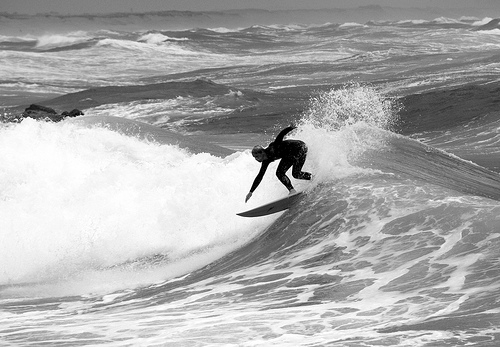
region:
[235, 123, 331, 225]
Man surfing on a wave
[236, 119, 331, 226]
Man standing on surf board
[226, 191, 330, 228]
Surf board on wave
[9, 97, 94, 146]
Rocks coming out of the water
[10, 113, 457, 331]
Large ocean waves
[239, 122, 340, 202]
Man wearing a black wetsuit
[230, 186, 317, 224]
Surf board the man is standing on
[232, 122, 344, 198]
Man with back leg in wave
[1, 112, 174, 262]
Wave crashing into rocks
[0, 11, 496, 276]
Ocean waves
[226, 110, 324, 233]
a black surfer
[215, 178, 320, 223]
a gray surfboard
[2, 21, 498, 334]
a gray beach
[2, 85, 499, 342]
large gray waves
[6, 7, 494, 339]
a scene outside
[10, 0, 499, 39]
a sky with clouds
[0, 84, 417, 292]
white splash of water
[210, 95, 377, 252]
a surfer riding a wave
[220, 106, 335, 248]
a surfer on top of a wave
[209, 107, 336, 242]
a surfer on a surfboard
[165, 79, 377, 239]
the man is surfing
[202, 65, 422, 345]
the man is surfing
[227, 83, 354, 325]
the man is surfing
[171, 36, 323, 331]
the man is surfing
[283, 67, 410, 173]
white cast off the waves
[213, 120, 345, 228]
a surfer in the water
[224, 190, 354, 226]
surfboard on the wave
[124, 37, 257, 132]
a wave in the ocean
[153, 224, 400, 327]
foamy white ocean water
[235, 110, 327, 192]
black wet suit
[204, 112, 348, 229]
a surfer riding a wave in the ocean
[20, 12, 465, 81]
gray waves in the back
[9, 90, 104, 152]
brown rocks in the ocean water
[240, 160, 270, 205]
a mans arm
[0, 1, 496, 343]
the picture is black and white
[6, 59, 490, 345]
the ocean has foam on it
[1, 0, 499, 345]
the water is grey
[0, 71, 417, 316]
the wave is crashing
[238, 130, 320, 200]
the man is wearing a wet suit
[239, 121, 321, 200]
the wet suit is black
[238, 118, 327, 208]
the man is wet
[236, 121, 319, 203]
the man is surfing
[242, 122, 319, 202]
the man is standing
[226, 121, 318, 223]
the man is on a surfboard